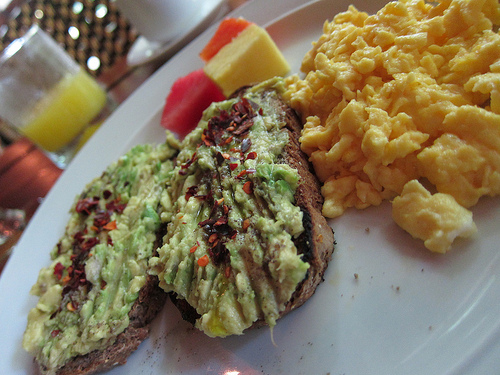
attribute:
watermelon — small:
[162, 71, 203, 129]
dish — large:
[2, 1, 497, 371]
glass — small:
[3, 18, 109, 150]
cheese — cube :
[205, 23, 294, 90]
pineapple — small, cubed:
[198, 20, 291, 97]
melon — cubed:
[205, 19, 287, 106]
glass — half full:
[0, 19, 114, 159]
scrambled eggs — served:
[289, 3, 497, 261]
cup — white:
[126, 9, 208, 59]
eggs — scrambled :
[282, 0, 499, 250]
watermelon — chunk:
[160, 70, 227, 139]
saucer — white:
[119, 9, 225, 61]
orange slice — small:
[202, 18, 250, 62]